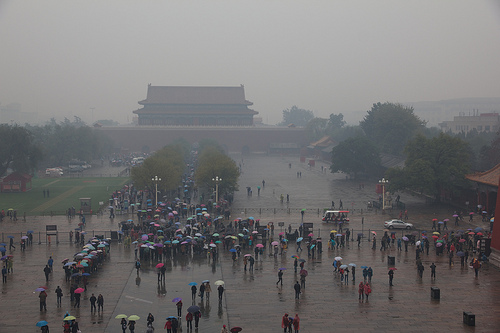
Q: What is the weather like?
A: It is cloudy.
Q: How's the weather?
A: It is cloudy.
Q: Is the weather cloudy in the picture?
A: Yes, it is cloudy.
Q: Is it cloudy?
A: Yes, it is cloudy.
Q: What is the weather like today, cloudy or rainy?
A: It is cloudy.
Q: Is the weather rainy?
A: No, it is cloudy.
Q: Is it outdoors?
A: Yes, it is outdoors.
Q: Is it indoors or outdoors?
A: It is outdoors.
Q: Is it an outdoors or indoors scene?
A: It is outdoors.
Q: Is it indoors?
A: No, it is outdoors.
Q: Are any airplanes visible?
A: No, there are no airplanes.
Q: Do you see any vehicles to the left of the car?
A: Yes, there is a vehicle to the left of the car.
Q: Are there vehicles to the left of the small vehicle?
A: Yes, there is a vehicle to the left of the car.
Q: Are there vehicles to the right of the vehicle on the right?
A: No, the vehicle is to the left of the car.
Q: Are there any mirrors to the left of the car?
A: No, there is a vehicle to the left of the car.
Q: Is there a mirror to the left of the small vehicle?
A: No, there is a vehicle to the left of the car.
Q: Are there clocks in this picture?
A: No, there are no clocks.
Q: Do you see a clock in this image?
A: No, there are no clocks.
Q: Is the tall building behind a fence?
A: Yes, the building is behind a fence.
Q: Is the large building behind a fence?
A: Yes, the building is behind a fence.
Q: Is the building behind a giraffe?
A: No, the building is behind a fence.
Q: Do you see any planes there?
A: No, there are no planes.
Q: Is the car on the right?
A: Yes, the car is on the right of the image.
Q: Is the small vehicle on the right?
A: Yes, the car is on the right of the image.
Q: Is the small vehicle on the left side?
A: No, the car is on the right of the image.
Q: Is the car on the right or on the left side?
A: The car is on the right of the image.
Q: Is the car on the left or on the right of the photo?
A: The car is on the right of the image.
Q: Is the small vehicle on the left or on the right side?
A: The car is on the right of the image.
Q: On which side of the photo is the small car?
A: The car is on the right of the image.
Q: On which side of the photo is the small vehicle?
A: The car is on the right of the image.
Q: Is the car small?
A: Yes, the car is small.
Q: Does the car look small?
A: Yes, the car is small.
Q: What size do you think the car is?
A: The car is small.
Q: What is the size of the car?
A: The car is small.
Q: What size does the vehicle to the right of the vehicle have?
A: The car has small size.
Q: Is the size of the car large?
A: No, the car is small.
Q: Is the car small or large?
A: The car is small.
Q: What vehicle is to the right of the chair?
A: The vehicle is a car.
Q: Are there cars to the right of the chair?
A: Yes, there is a car to the right of the chair.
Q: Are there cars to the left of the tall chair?
A: No, the car is to the right of the chair.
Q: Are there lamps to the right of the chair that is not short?
A: No, there is a car to the right of the chair.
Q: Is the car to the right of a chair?
A: Yes, the car is to the right of a chair.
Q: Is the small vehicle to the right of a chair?
A: Yes, the car is to the right of a chair.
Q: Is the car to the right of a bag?
A: No, the car is to the right of a chair.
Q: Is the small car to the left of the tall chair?
A: No, the car is to the right of the chair.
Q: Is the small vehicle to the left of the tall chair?
A: No, the car is to the right of the chair.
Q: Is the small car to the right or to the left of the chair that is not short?
A: The car is to the right of the chair.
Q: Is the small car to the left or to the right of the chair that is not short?
A: The car is to the right of the chair.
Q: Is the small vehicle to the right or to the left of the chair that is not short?
A: The car is to the right of the chair.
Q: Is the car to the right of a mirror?
A: No, the car is to the right of the vehicle.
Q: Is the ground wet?
A: Yes, the ground is wet.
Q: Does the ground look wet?
A: Yes, the ground is wet.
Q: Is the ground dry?
A: No, the ground is wet.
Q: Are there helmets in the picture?
A: No, there are no helmets.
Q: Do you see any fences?
A: Yes, there is a fence.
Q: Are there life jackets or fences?
A: Yes, there is a fence.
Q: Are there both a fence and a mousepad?
A: No, there is a fence but no mouse pads.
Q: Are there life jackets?
A: No, there are no life jackets.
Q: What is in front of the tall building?
A: The fence is in front of the building.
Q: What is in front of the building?
A: The fence is in front of the building.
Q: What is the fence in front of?
A: The fence is in front of the building.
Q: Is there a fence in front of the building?
A: Yes, there is a fence in front of the building.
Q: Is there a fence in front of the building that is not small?
A: Yes, there is a fence in front of the building.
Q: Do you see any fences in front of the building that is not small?
A: Yes, there is a fence in front of the building.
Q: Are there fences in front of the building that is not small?
A: Yes, there is a fence in front of the building.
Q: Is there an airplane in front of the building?
A: No, there is a fence in front of the building.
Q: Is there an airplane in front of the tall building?
A: No, there is a fence in front of the building.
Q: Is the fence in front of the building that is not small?
A: Yes, the fence is in front of the building.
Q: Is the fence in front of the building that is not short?
A: Yes, the fence is in front of the building.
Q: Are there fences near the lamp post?
A: Yes, there is a fence near the lamp post.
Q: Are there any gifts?
A: No, there are no gifts.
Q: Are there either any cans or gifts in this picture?
A: No, there are no gifts or cans.